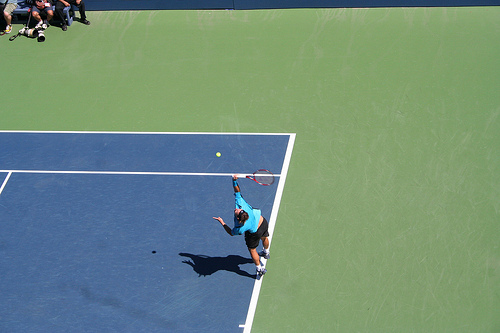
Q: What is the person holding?
A: Racket.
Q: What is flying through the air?
A: Ball.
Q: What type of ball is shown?
A: Tennis ball.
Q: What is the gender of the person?
A: Male.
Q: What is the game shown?
A: Tennis.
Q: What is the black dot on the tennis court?
A: Shadow of the ball.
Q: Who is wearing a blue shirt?
A: The tennis player.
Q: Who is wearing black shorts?
A: The tennis player.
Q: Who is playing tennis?
A: A tennis player.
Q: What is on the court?
A: White baseline.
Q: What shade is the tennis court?
A: Blue.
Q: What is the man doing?
A: Playing tennis.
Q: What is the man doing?
A: Playing tennis.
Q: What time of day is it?
A: Day time.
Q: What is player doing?
A: Hitting the ball.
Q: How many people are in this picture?
A: Four.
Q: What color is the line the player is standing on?
A: White.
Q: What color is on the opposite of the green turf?
A: Blue.